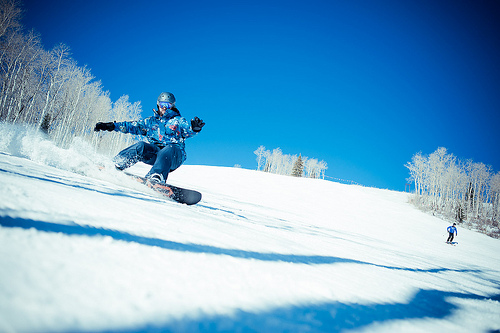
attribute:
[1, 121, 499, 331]
snow — white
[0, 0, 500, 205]
sky — blue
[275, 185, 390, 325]
snow — white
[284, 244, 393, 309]
snow — white